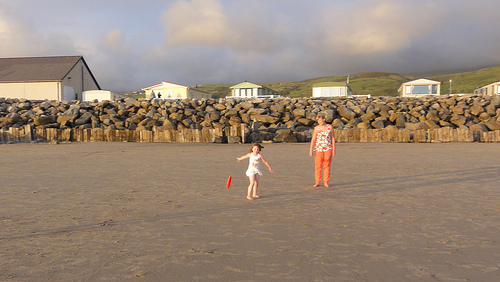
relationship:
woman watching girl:
[308, 115, 337, 189] [235, 142, 274, 203]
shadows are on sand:
[329, 165, 499, 204] [1, 140, 498, 280]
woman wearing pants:
[308, 115, 337, 189] [313, 149, 331, 185]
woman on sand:
[308, 115, 337, 189] [1, 140, 498, 280]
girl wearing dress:
[235, 142, 274, 203] [246, 153, 262, 179]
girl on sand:
[235, 142, 274, 203] [1, 140, 498, 280]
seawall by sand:
[2, 94, 500, 145] [1, 140, 498, 280]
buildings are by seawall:
[226, 80, 283, 98] [2, 94, 500, 145]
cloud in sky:
[162, 3, 296, 53] [1, 0, 499, 90]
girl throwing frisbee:
[235, 142, 274, 203] [226, 176, 232, 189]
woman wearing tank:
[308, 115, 337, 189] [314, 127, 333, 151]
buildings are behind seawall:
[226, 80, 283, 98] [2, 94, 500, 145]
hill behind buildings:
[120, 64, 499, 96] [226, 80, 283, 98]